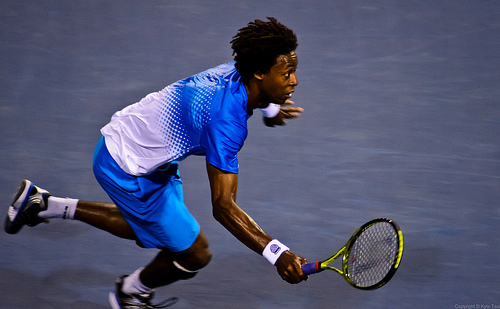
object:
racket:
[300, 217, 405, 291]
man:
[3, 12, 310, 308]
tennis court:
[3, 0, 500, 309]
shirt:
[98, 61, 253, 178]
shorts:
[90, 134, 203, 254]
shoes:
[107, 272, 181, 308]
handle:
[300, 260, 323, 275]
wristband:
[260, 237, 291, 266]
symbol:
[268, 243, 282, 254]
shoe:
[4, 178, 51, 235]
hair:
[228, 15, 299, 84]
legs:
[105, 173, 214, 308]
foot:
[3, 178, 51, 236]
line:
[392, 229, 405, 269]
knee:
[173, 240, 213, 272]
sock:
[37, 195, 81, 221]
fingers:
[290, 260, 309, 282]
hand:
[274, 249, 311, 285]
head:
[342, 216, 405, 292]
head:
[230, 14, 299, 105]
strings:
[384, 248, 389, 252]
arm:
[202, 125, 285, 262]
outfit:
[89, 61, 256, 254]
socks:
[120, 265, 157, 297]